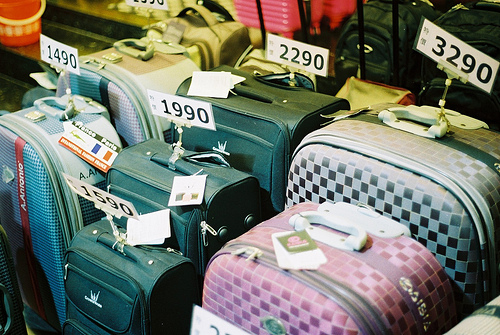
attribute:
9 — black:
[297, 48, 313, 73]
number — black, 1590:
[79, 182, 134, 216]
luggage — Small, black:
[62, 221, 199, 333]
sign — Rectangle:
[146, 92, 220, 131]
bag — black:
[258, 45, 499, 318]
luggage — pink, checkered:
[206, 200, 451, 329]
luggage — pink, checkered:
[278, 199, 429, 314]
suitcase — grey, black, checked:
[286, 97, 499, 309]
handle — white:
[378, 100, 470, 157]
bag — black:
[41, 173, 197, 333]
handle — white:
[290, 208, 370, 250]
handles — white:
[281, 205, 381, 260]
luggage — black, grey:
[284, 117, 484, 297]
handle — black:
[349, 3, 405, 86]